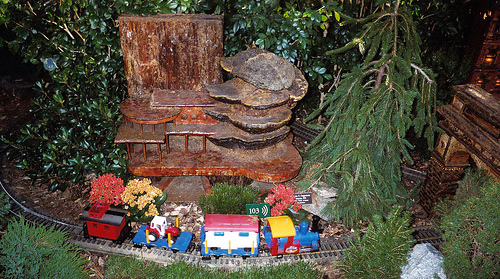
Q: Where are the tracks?
A: Through the bushes.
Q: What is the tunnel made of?
A: Wood.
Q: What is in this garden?
A: Wood crafted object.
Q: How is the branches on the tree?
A: Bent.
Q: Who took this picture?
A: A kid.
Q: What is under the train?
A: A track.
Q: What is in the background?
A: Trees.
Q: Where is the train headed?
A: The tunnel.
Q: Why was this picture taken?
A: Advertisement.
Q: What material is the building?
A: Wood.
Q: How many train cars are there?
A: 4.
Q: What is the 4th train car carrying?
A: A car.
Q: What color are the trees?
A: Green.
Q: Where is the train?
A: On the track.